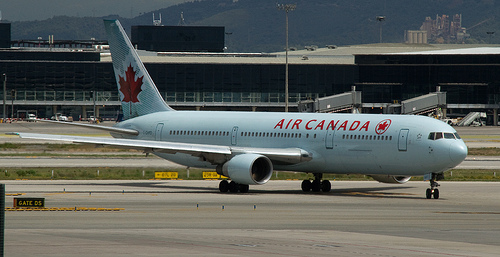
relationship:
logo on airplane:
[270, 110, 401, 144] [57, 22, 483, 203]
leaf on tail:
[114, 62, 153, 107] [92, 14, 185, 136]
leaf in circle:
[114, 62, 153, 107] [375, 119, 394, 141]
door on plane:
[324, 125, 340, 157] [57, 22, 483, 203]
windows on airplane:
[427, 127, 467, 150] [57, 22, 483, 203]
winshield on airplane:
[427, 127, 467, 150] [57, 22, 483, 203]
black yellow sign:
[15, 197, 43, 209] [10, 194, 47, 211]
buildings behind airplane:
[48, 32, 500, 167] [57, 22, 483, 203]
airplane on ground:
[57, 22, 483, 203] [23, 163, 490, 250]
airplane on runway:
[57, 22, 483, 203] [23, 163, 490, 250]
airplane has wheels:
[57, 22, 483, 203] [215, 165, 345, 202]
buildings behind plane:
[48, 32, 500, 167] [57, 22, 483, 203]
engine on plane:
[220, 147, 291, 198] [57, 22, 483, 203]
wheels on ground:
[215, 165, 345, 202] [23, 163, 490, 250]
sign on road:
[10, 194, 47, 211] [23, 163, 490, 250]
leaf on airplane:
[114, 62, 153, 107] [57, 22, 483, 203]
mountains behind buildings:
[144, 2, 499, 40] [48, 32, 500, 167]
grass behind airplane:
[59, 157, 209, 181] [57, 22, 483, 203]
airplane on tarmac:
[57, 22, 483, 203] [23, 163, 490, 250]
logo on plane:
[270, 110, 401, 144] [57, 22, 483, 203]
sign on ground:
[10, 194, 47, 211] [23, 163, 490, 250]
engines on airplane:
[220, 147, 291, 198] [57, 22, 483, 203]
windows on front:
[427, 127, 467, 150] [383, 108, 481, 211]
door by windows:
[324, 125, 340, 157] [427, 127, 467, 150]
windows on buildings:
[427, 127, 467, 150] [48, 32, 500, 167]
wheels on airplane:
[215, 165, 345, 202] [57, 22, 483, 203]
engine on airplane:
[220, 147, 291, 198] [57, 22, 483, 203]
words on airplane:
[270, 110, 401, 144] [57, 22, 483, 203]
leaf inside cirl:
[114, 62, 153, 107] [374, 110, 390, 136]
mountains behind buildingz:
[144, 2, 499, 40] [48, 32, 500, 167]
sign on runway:
[10, 194, 47, 211] [23, 163, 490, 250]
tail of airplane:
[92, 14, 185, 136] [57, 22, 483, 203]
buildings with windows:
[48, 32, 500, 167] [427, 127, 467, 150]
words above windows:
[270, 110, 401, 144] [427, 127, 467, 150]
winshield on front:
[421, 124, 462, 142] [383, 108, 481, 211]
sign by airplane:
[10, 194, 47, 211] [57, 22, 483, 203]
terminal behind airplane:
[48, 32, 500, 167] [57, 22, 483, 203]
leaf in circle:
[114, 62, 153, 107] [372, 117, 394, 136]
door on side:
[324, 125, 340, 157] [185, 107, 446, 174]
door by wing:
[324, 125, 340, 157] [74, 130, 298, 171]